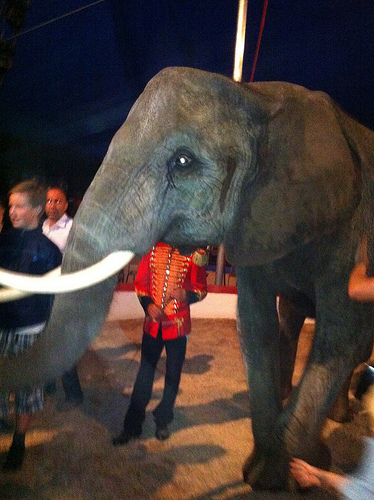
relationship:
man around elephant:
[45, 177, 88, 407] [8, 64, 355, 404]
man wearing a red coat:
[109, 229, 212, 446] [131, 243, 210, 339]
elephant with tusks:
[8, 64, 355, 404] [3, 232, 130, 298]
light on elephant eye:
[180, 158, 185, 163] [171, 147, 202, 173]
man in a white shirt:
[45, 177, 98, 407] [41, 218, 77, 254]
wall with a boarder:
[6, 69, 88, 247] [19, 39, 99, 129]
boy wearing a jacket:
[2, 177, 67, 475] [5, 234, 65, 313]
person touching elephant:
[354, 251, 374, 302] [8, 64, 355, 404]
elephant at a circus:
[8, 64, 355, 404] [60, 59, 119, 128]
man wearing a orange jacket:
[109, 229, 212, 446] [141, 247, 187, 310]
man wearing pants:
[109, 229, 212, 446] [128, 327, 191, 424]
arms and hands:
[136, 246, 213, 282] [147, 286, 194, 321]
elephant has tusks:
[8, 64, 355, 404] [3, 232, 130, 298]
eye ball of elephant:
[171, 147, 202, 173] [8, 64, 355, 404]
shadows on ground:
[91, 369, 124, 466] [74, 311, 286, 498]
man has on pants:
[109, 229, 212, 446] [128, 327, 191, 424]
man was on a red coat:
[109, 229, 212, 446] [136, 259, 211, 338]